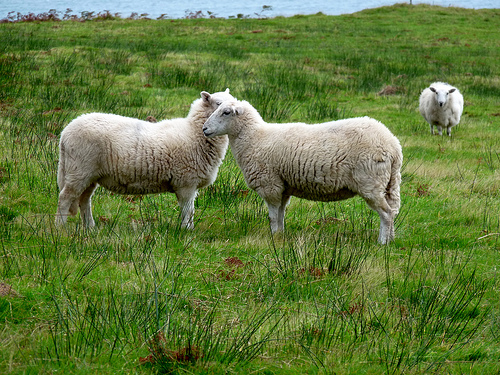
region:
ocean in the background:
[0, 0, 499, 22]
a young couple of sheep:
[52, 86, 404, 246]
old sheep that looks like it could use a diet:
[416, 80, 466, 137]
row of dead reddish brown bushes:
[0, 7, 248, 24]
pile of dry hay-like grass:
[378, 84, 404, 96]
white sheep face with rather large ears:
[427, 85, 455, 107]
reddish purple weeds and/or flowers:
[135, 327, 202, 368]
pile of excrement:
[0, 275, 17, 300]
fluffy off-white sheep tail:
[387, 149, 402, 219]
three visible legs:
[52, 189, 197, 231]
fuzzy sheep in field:
[408, 70, 475, 140]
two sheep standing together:
[39, 80, 413, 257]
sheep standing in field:
[8, 4, 495, 368]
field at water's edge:
[1, 2, 499, 74]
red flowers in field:
[118, 322, 210, 372]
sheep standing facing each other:
[41, 65, 418, 255]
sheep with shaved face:
[176, 77, 286, 157]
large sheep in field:
[5, 7, 491, 369]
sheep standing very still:
[3, 3, 496, 363]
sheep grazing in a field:
[3, 7, 498, 332]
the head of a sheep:
[198, 94, 255, 141]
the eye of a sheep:
[218, 105, 233, 119]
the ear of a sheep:
[196, 87, 216, 104]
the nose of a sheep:
[198, 122, 210, 132]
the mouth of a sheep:
[199, 127, 218, 139]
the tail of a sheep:
[381, 140, 411, 220]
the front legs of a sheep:
[262, 185, 297, 241]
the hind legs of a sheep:
[358, 185, 403, 247]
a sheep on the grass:
[198, 97, 418, 244]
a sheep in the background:
[412, 71, 471, 143]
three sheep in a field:
[29, 53, 469, 260]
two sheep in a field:
[25, 84, 403, 234]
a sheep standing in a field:
[410, 66, 482, 157]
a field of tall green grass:
[103, 248, 479, 370]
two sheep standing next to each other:
[48, 97, 410, 230]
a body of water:
[8, 0, 360, 15]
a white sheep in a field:
[408, 52, 465, 147]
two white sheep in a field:
[31, 90, 413, 245]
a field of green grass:
[58, 21, 415, 83]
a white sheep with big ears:
[412, 70, 466, 138]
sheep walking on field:
[420, 78, 464, 134]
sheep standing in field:
[209, 100, 406, 243]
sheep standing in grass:
[51, 90, 238, 239]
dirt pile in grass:
[221, 253, 243, 271]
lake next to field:
[3, 1, 499, 26]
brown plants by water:
[8, 11, 167, 26]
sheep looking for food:
[51, 87, 238, 232]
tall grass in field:
[151, 60, 224, 90]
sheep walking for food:
[421, 81, 466, 136]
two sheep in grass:
[52, 89, 407, 246]